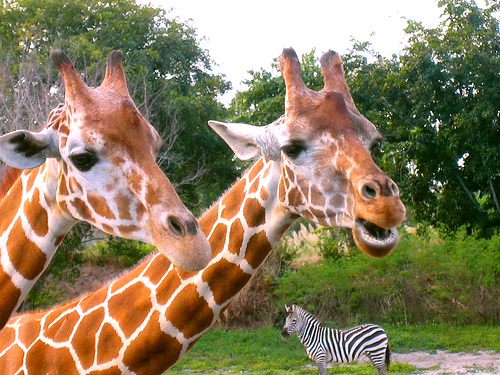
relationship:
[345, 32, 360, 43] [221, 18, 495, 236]
leaves on tree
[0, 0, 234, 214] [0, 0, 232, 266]
leaves are on tree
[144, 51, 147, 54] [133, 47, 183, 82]
leaf growing on tree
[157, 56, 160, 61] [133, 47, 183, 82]
leaf growing on tree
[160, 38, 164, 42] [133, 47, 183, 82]
leaf growing on tree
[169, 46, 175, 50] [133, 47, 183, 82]
leaf growing on tree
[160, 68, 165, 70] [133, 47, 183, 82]
leaf growing on tree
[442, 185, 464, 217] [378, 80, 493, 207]
leaves on tree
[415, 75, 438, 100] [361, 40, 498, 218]
leaves on tree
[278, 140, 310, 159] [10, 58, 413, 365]
eye on giraffe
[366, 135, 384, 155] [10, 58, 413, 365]
eye on giraffe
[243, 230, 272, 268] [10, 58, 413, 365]
spot on giraffe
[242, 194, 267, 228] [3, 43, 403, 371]
spot on giraffe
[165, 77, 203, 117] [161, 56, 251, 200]
leaves on tree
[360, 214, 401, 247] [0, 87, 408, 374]
mouth of giraffe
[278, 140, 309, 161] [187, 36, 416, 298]
eye of giraffe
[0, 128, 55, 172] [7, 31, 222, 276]
ear of giraffe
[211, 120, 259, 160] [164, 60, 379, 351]
ear of giraffe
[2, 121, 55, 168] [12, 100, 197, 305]
ear of giraffe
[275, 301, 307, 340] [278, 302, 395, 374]
head of zebra